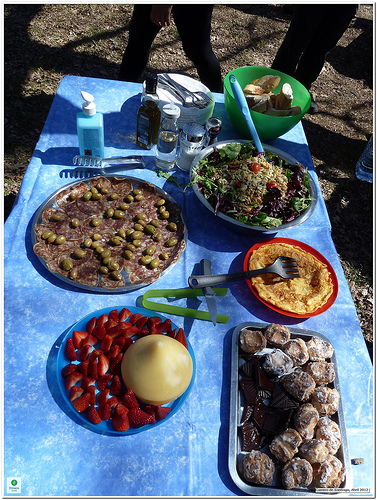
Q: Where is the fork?
A: In a pie.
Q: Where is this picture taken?
A: A picnic.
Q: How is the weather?
A: Sunny.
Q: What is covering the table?
A: A tablecloth.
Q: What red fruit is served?
A: Strawberries.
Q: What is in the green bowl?
A: Bread.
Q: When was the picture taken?
A: Afternoon.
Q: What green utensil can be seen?
A: Tongs.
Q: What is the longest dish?
A: The silver tray.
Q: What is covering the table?
A: Blue and white tablecloth.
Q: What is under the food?
A: A blue tablecloth.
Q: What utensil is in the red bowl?
A: A fork.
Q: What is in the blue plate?
A: Strawberries.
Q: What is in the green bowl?
A: Bread.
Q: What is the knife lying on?
A: Tongs.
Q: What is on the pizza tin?
A: Olives and meat.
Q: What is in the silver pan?
A: Doughnuts.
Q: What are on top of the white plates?
A: Utensils.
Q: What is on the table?
A: Food.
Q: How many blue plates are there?
A: One.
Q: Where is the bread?
A: Green bowl.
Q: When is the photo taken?
A: Daytime.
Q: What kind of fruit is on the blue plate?
A: Strawberries.